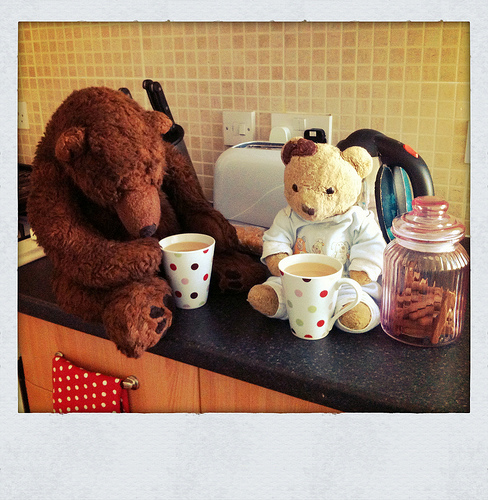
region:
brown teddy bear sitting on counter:
[26, 73, 254, 365]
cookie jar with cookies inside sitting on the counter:
[388, 185, 473, 365]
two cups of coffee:
[158, 227, 349, 354]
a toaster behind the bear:
[215, 130, 382, 238]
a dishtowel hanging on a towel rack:
[41, 339, 146, 412]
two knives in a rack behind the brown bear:
[132, 67, 208, 207]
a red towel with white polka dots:
[41, 344, 142, 413]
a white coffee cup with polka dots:
[153, 232, 222, 313]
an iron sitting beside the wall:
[338, 121, 444, 315]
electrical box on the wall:
[266, 106, 334, 156]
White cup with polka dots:
[267, 245, 362, 347]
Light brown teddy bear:
[245, 126, 392, 333]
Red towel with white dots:
[19, 342, 160, 418]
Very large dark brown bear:
[22, 72, 266, 364]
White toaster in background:
[199, 124, 309, 241]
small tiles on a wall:
[160, 30, 463, 111]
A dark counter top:
[30, 250, 471, 403]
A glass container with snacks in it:
[372, 190, 468, 348]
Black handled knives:
[102, 65, 217, 203]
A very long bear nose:
[110, 171, 179, 250]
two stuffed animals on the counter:
[38, 80, 391, 354]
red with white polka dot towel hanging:
[43, 347, 132, 423]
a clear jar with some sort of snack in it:
[385, 194, 468, 349]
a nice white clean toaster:
[210, 133, 309, 225]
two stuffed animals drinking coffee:
[28, 81, 376, 343]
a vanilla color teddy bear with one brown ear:
[254, 136, 378, 333]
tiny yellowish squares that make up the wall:
[20, 32, 466, 206]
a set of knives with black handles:
[112, 74, 208, 182]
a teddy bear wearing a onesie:
[252, 138, 384, 336]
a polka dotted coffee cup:
[279, 258, 362, 339]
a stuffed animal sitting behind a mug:
[23, 83, 256, 352]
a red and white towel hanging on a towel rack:
[44, 349, 133, 404]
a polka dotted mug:
[275, 248, 357, 336]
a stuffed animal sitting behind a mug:
[248, 135, 381, 341]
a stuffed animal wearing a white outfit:
[245, 134, 385, 343]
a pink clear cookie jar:
[377, 192, 468, 350]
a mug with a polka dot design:
[158, 231, 217, 310]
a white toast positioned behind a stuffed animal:
[213, 135, 384, 345]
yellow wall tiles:
[20, 23, 471, 242]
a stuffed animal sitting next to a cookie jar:
[248, 136, 466, 350]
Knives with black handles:
[112, 75, 204, 169]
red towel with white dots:
[34, 340, 144, 420]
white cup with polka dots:
[155, 218, 224, 321]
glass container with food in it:
[382, 184, 474, 356]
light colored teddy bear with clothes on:
[243, 133, 384, 340]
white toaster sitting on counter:
[208, 134, 306, 237]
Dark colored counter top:
[21, 244, 471, 406]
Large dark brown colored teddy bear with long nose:
[21, 79, 253, 363]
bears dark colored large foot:
[97, 278, 186, 363]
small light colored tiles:
[248, 26, 445, 115]